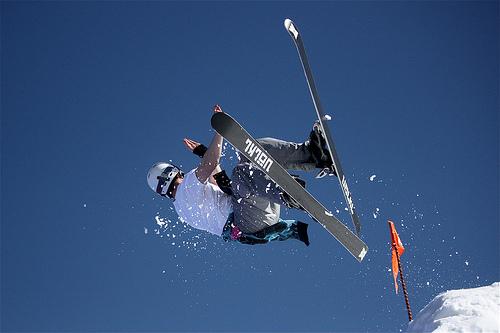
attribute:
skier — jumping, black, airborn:
[128, 18, 376, 265]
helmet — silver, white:
[139, 160, 184, 198]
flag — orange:
[387, 222, 413, 329]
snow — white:
[386, 282, 495, 331]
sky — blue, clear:
[1, 1, 498, 277]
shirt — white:
[170, 169, 237, 241]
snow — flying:
[367, 170, 478, 288]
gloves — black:
[188, 144, 213, 160]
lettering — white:
[243, 136, 274, 173]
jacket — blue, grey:
[221, 215, 311, 249]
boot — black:
[307, 122, 334, 180]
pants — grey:
[228, 135, 310, 234]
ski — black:
[203, 101, 369, 264]